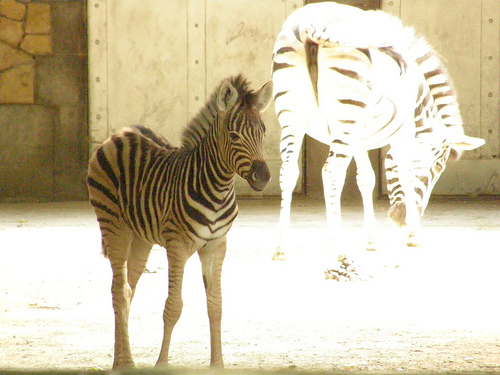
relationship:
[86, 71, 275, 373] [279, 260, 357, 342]
zebra stand in dirt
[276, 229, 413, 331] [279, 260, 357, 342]
light brightens dirt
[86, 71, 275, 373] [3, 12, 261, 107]
zebra walks away from building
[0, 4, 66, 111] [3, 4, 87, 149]
art on wall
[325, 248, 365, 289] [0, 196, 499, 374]
rocks on ground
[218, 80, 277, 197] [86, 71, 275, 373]
head of zebra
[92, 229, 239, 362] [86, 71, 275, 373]
legs of zebra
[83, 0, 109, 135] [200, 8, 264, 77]
rivets on wall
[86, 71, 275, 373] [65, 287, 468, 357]
zebra on ground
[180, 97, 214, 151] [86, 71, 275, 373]
mane of zebra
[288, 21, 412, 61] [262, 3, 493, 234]
tail of mother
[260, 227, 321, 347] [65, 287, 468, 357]
sunlight shines on ground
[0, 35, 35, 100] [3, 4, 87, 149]
stones on wall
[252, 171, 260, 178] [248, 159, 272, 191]
nostril on snout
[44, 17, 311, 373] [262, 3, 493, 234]
zebra has mother